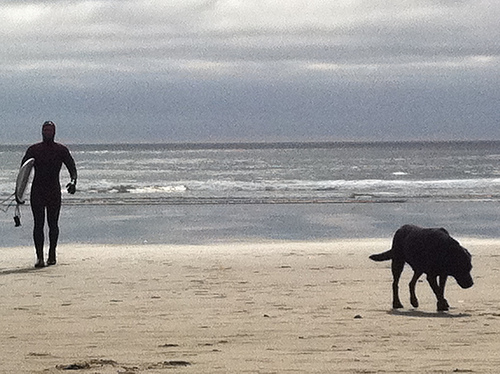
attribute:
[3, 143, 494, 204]
waves — not large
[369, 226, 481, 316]
dog — medium, black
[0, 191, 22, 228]
rope — small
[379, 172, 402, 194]
ground —  sandy,  tan, soft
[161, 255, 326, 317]
sand — brownish, gray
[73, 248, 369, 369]
ground — soft, tan, sandy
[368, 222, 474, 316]
dog — black,  medium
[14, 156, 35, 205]
surfboard —  long, white, wet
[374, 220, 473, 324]
dog — black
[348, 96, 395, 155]
wall —  black, skinny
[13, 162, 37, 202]
surfboard — white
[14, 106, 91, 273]
suit — black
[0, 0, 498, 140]
sky — cloudy, gray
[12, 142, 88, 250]
wetsuit — black